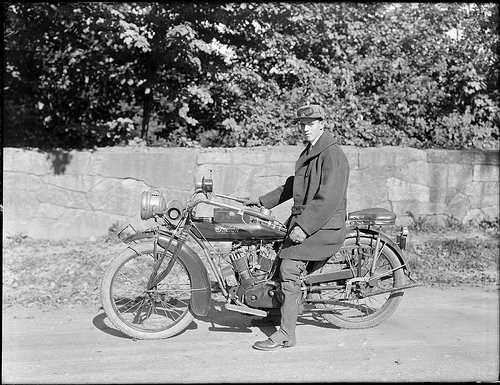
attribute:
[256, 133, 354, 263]
coat — black 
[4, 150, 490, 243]
wall — stone 